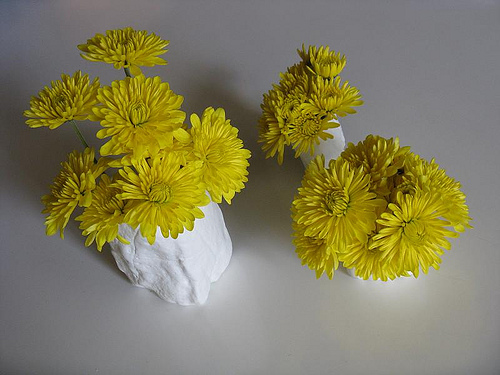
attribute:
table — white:
[4, 9, 85, 361]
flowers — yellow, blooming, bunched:
[24, 24, 472, 307]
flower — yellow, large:
[24, 67, 98, 150]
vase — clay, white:
[103, 213, 258, 317]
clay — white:
[203, 227, 252, 275]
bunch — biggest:
[36, 17, 214, 288]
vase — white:
[286, 110, 353, 169]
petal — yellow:
[118, 232, 132, 248]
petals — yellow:
[228, 151, 252, 187]